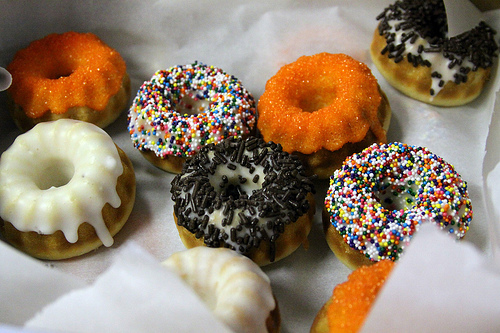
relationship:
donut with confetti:
[127, 49, 254, 154] [146, 83, 174, 138]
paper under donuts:
[174, 11, 301, 58] [126, 43, 389, 262]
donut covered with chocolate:
[171, 135, 318, 250] [192, 186, 261, 212]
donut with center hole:
[127, 49, 254, 154] [168, 85, 211, 114]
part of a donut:
[195, 163, 206, 177] [171, 135, 318, 250]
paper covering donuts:
[174, 11, 301, 58] [126, 43, 389, 262]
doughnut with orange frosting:
[13, 28, 130, 108] [78, 82, 93, 95]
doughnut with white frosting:
[174, 243, 278, 328] [237, 270, 253, 311]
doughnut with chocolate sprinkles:
[368, 0, 499, 108] [397, 20, 437, 57]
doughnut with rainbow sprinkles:
[332, 140, 473, 251] [351, 179, 371, 213]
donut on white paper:
[125, 60, 256, 174] [440, 1, 485, 34]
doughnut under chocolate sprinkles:
[368, 0, 499, 108] [397, 20, 437, 57]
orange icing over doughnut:
[35, 43, 85, 69] [13, 28, 130, 108]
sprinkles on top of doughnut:
[351, 179, 371, 213] [332, 140, 473, 251]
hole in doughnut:
[34, 153, 79, 188] [7, 115, 125, 214]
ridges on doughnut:
[351, 109, 380, 139] [13, 28, 130, 108]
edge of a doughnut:
[262, 221, 287, 234] [171, 135, 318, 250]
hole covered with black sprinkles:
[227, 173, 257, 196] [186, 171, 208, 210]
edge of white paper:
[420, 215, 449, 247] [360, 214, 486, 331]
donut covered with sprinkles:
[127, 49, 254, 154] [160, 71, 220, 90]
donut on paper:
[127, 49, 254, 154] [174, 11, 301, 58]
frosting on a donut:
[274, 87, 291, 113] [263, 49, 377, 144]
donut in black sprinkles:
[171, 135, 318, 250] [186, 171, 208, 210]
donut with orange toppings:
[263, 49, 377, 144] [328, 57, 357, 86]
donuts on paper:
[126, 43, 389, 262] [174, 11, 301, 58]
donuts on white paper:
[126, 43, 389, 262] [440, 1, 485, 34]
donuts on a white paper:
[126, 43, 389, 262] [440, 1, 485, 34]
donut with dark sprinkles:
[171, 135, 318, 250] [202, 193, 247, 209]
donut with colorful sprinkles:
[127, 49, 254, 154] [196, 66, 219, 87]